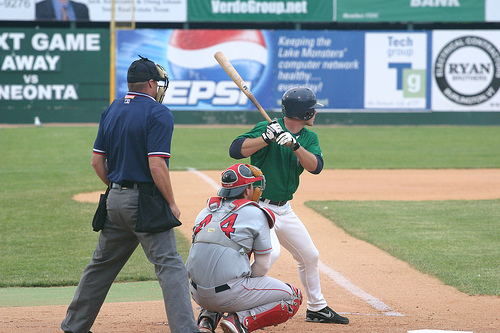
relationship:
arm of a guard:
[145, 105, 180, 218] [59, 56, 206, 333]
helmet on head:
[279, 85, 325, 120] [280, 85, 325, 130]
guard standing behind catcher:
[59, 56, 206, 333] [179, 153, 309, 330]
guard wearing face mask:
[59, 56, 206, 333] [134, 57, 172, 102]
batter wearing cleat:
[217, 79, 357, 327] [305, 305, 350, 325]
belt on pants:
[180, 261, 258, 298] [181, 271, 307, 330]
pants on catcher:
[181, 271, 307, 330] [179, 153, 309, 330]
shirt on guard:
[91, 91, 174, 182] [59, 56, 206, 333]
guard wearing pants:
[59, 56, 206, 333] [44, 185, 201, 331]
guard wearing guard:
[59, 56, 206, 333] [133, 62, 177, 104]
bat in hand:
[196, 45, 286, 135] [270, 128, 301, 150]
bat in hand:
[196, 45, 286, 135] [258, 113, 285, 145]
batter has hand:
[217, 79, 357, 327] [270, 128, 301, 150]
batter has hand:
[217, 79, 357, 327] [258, 113, 285, 145]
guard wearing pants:
[59, 56, 206, 333] [103, 190, 173, 331]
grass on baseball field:
[298, 192, 498, 298] [0, 125, 500, 333]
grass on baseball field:
[0, 125, 497, 295] [0, 125, 500, 333]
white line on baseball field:
[187, 160, 401, 314] [0, 125, 496, 329]